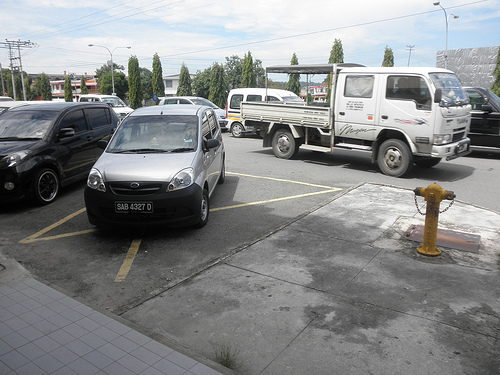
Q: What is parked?
A: A silver car.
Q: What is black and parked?
A: A car.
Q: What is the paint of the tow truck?
A: White.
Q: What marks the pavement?
A: Wet marks.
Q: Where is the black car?
A: In a parking lot.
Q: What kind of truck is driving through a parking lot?
A: A flat bed truck.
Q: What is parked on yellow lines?
A: A vehicle.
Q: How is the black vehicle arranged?
A: Parked.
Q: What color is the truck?
A: White.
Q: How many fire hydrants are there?
A: One.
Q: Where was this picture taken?
A: Street.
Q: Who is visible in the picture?
A: No one.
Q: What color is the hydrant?
A: Yellow.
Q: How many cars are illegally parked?
A: One.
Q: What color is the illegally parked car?
A: Silver.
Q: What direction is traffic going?
A: Right.